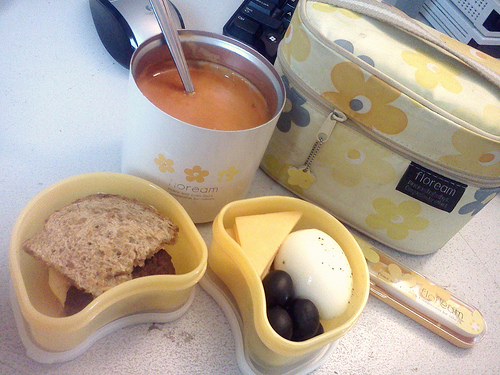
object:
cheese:
[231, 209, 304, 281]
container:
[208, 196, 370, 369]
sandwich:
[23, 192, 180, 315]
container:
[7, 170, 209, 353]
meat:
[62, 248, 175, 315]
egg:
[47, 269, 70, 307]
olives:
[261, 270, 294, 308]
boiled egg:
[273, 229, 352, 319]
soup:
[139, 55, 270, 130]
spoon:
[149, 0, 194, 94]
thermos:
[125, 28, 287, 225]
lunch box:
[260, 1, 499, 258]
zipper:
[271, 45, 500, 188]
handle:
[320, 0, 499, 87]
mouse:
[89, 0, 185, 70]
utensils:
[349, 234, 483, 350]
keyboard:
[224, 1, 300, 65]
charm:
[286, 166, 316, 189]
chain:
[304, 136, 324, 171]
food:
[268, 308, 293, 341]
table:
[0, 2, 498, 374]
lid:
[199, 267, 340, 375]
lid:
[8, 279, 198, 366]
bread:
[23, 195, 180, 298]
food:
[291, 296, 320, 339]